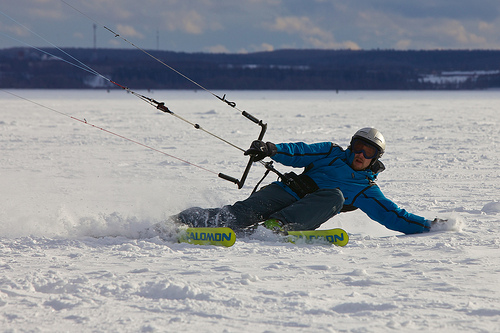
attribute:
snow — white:
[6, 232, 498, 329]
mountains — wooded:
[0, 44, 500, 93]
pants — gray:
[203, 174, 339, 225]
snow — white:
[17, 116, 166, 325]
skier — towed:
[206, 131, 481, 262]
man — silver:
[203, 94, 448, 279]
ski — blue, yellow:
[161, 222, 252, 263]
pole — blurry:
[73, 14, 126, 66]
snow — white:
[11, 91, 493, 275]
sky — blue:
[6, 1, 494, 41]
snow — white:
[23, 226, 110, 276]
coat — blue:
[237, 116, 407, 233]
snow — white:
[2, 90, 496, 330]